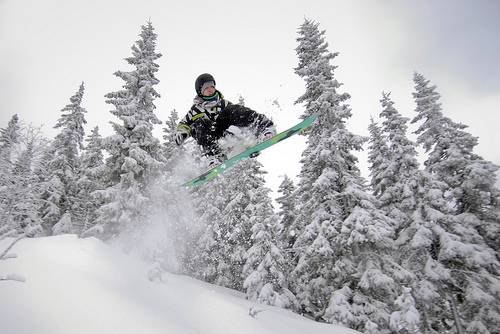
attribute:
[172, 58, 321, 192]
snowboarder — ridig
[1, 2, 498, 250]
air — misting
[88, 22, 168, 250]
tree — pine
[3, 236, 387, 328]
snow — smooth, snowy, white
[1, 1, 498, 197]
sky — white, cloudy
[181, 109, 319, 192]
snowboard — green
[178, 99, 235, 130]
jacket — green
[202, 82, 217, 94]
hat — gray